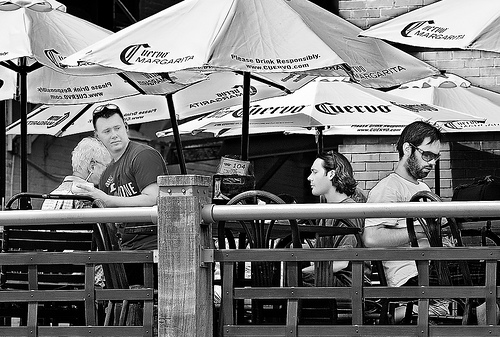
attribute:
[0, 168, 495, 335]
patio — outdoor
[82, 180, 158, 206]
arm — bent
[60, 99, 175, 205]
person — sitting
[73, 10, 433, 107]
umbrella — up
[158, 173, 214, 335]
pole — wood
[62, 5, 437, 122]
umbrellas — branded